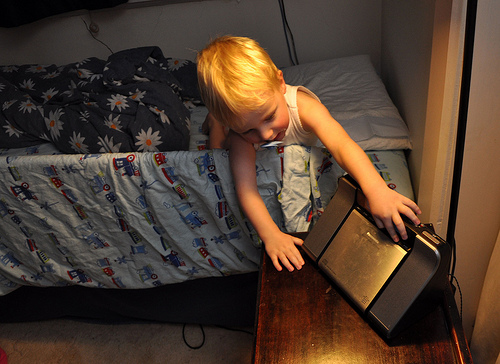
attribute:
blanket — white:
[21, 87, 411, 314]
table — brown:
[255, 241, 464, 362]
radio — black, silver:
[278, 191, 471, 318]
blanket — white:
[4, 138, 308, 278]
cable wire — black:
[275, 0, 304, 82]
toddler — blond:
[194, 30, 421, 278]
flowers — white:
[94, 133, 124, 153]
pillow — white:
[103, 2, 304, 76]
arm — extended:
[304, 91, 416, 227]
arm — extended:
[233, 137, 273, 247]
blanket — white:
[1, 45, 203, 150]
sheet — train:
[2, 155, 415, 297]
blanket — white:
[5, 158, 260, 276]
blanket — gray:
[26, 61, 240, 166]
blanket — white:
[2, 59, 415, 300]